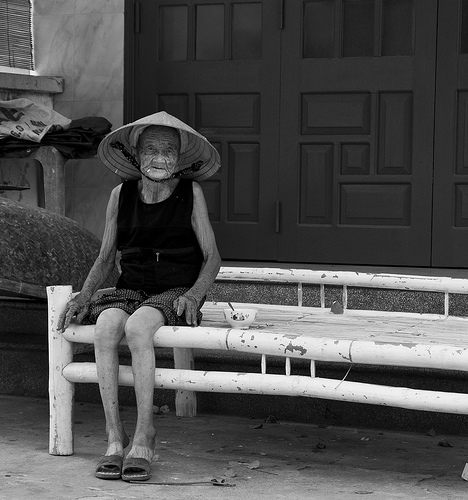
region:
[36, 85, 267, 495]
an old woman sitting on a bench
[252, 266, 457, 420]
a wooden bench with peeling paint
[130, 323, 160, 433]
the left leg of a person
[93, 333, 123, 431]
the right leg of a person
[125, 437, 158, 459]
the left foot of a person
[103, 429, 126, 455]
a person's right foot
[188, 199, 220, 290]
the left arm of a person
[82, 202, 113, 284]
the right arm of a person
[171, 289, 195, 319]
the left hand of a person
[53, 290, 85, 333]
the right hand of a person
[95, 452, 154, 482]
a pair of shoes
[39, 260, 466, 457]
an old wooden bench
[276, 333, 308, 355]
a patch of peeling paint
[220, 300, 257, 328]
a small bowl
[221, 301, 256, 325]
a spoon in a small bowl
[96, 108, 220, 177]
a large straw hat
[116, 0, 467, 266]
a pair of large doors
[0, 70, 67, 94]
the ledge of a window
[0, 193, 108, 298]
a large basket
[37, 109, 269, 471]
a woman sitting on a bench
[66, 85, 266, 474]
an old woman with a hat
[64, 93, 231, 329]
an old woman with a hat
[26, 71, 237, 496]
woman sitting on a chair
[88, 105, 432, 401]
a woma nsitting on a bench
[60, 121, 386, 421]
a woman sitting on a wood bench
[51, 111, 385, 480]
a woman sitting on an outside bench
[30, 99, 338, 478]
a woman sitting outside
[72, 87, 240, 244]
a woman wearing a hat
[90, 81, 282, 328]
a woman wearing a shirt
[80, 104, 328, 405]
a woman wearing a skirt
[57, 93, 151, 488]
a woman wearing slippers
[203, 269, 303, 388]
a bowl on the bench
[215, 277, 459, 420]
a small bowl on the bench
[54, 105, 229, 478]
a very thin older woman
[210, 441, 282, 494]
debris on the ground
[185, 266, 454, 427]
an old wooden bamboo bench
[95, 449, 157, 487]
a pair of cloth sandals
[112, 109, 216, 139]
a pointy straw hat on head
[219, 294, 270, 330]
a bowl with a spoon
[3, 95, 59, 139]
a crumpled newspaper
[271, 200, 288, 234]
the bottom hinge in door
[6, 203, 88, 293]
a large wicker basket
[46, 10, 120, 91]
a marble wall behind the woman